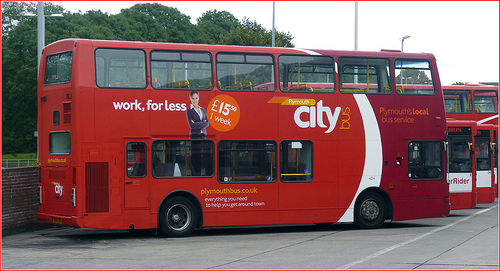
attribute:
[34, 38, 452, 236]
bus — red, parked, double decker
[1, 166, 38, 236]
wall — brick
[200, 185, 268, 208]
lettering — orange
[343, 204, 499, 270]
line — white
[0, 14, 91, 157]
tree — green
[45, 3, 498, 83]
sky — overcast